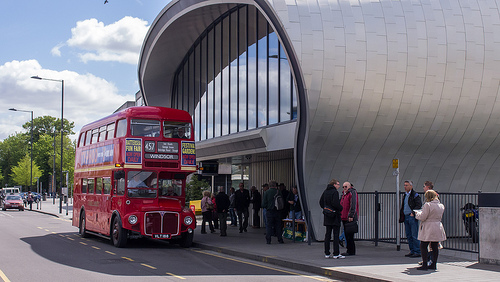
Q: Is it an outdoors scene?
A: Yes, it is outdoors.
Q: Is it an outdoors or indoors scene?
A: It is outdoors.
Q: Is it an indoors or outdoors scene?
A: It is outdoors.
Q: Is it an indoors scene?
A: No, it is outdoors.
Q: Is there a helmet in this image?
A: No, there are no helmets.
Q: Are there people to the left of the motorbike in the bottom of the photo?
A: Yes, there is a person to the left of the motorcycle.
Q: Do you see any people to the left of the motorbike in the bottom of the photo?
A: Yes, there is a person to the left of the motorcycle.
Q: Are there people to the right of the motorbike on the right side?
A: No, the person is to the left of the motorbike.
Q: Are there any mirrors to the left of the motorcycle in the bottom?
A: No, there is a person to the left of the motorbike.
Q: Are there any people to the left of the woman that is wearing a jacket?
A: Yes, there is a person to the left of the woman.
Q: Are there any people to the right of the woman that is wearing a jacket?
A: No, the person is to the left of the woman.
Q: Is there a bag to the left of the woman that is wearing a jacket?
A: No, there is a person to the left of the woman.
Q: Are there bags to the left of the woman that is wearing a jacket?
A: No, there is a person to the left of the woman.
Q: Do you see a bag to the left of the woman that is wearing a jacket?
A: No, there is a person to the left of the woman.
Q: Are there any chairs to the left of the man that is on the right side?
A: No, there is a person to the left of the man.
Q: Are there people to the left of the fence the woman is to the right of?
A: Yes, there is a person to the left of the fence.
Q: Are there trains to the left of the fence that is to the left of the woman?
A: No, there is a person to the left of the fence.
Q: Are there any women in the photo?
A: Yes, there is a woman.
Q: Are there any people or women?
A: Yes, there is a woman.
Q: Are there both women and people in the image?
A: Yes, there are both a woman and people.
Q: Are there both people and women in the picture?
A: Yes, there are both a woman and people.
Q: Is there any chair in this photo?
A: No, there are no chairs.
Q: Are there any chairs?
A: No, there are no chairs.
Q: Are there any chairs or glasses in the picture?
A: No, there are no chairs or glasses.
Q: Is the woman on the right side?
A: Yes, the woman is on the right of the image.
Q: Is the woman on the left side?
A: No, the woman is on the right of the image.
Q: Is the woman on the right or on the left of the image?
A: The woman is on the right of the image.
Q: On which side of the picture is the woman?
A: The woman is on the right of the image.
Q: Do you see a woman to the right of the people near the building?
A: Yes, there is a woman to the right of the people.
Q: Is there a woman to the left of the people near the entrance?
A: No, the woman is to the right of the people.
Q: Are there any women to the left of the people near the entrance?
A: No, the woman is to the right of the people.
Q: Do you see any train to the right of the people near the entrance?
A: No, there is a woman to the right of the people.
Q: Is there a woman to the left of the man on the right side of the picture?
A: Yes, there is a woman to the left of the man.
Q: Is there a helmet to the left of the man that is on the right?
A: No, there is a woman to the left of the man.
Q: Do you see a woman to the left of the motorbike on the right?
A: Yes, there is a woman to the left of the motorbike.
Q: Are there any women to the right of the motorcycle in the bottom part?
A: No, the woman is to the left of the motorbike.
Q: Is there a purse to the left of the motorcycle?
A: No, there is a woman to the left of the motorcycle.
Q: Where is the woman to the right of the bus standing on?
A: The woman is standing on the sidewalk.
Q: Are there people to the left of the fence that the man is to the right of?
A: Yes, there are people to the left of the fence.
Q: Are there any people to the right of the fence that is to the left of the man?
A: No, the people are to the left of the fence.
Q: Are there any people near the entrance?
A: Yes, there are people near the entrance.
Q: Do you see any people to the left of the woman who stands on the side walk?
A: Yes, there are people to the left of the woman.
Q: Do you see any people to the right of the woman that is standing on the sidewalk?
A: No, the people are to the left of the woman.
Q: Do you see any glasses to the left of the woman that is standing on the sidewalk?
A: No, there are people to the left of the woman.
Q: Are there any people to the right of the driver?
A: Yes, there are people to the right of the driver.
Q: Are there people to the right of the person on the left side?
A: Yes, there are people to the right of the driver.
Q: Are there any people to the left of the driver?
A: No, the people are to the right of the driver.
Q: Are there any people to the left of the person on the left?
A: No, the people are to the right of the driver.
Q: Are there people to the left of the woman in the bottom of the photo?
A: Yes, there are people to the left of the woman.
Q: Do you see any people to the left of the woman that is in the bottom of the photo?
A: Yes, there are people to the left of the woman.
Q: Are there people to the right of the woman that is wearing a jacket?
A: No, the people are to the left of the woman.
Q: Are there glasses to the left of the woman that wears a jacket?
A: No, there are people to the left of the woman.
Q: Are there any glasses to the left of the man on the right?
A: No, there are people to the left of the man.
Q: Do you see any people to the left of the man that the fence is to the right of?
A: Yes, there are people to the left of the man.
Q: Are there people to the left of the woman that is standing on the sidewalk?
A: Yes, there is a person to the left of the woman.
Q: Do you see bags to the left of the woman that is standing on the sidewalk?
A: No, there is a person to the left of the woman.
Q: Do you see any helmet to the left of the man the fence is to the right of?
A: No, there is a person to the left of the man.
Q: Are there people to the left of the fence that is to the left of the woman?
A: Yes, there is a person to the left of the fence.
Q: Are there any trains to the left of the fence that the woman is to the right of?
A: No, there is a person to the left of the fence.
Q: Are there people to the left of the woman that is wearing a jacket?
A: Yes, there is a person to the left of the woman.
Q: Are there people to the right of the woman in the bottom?
A: No, the person is to the left of the woman.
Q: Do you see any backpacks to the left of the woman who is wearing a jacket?
A: No, there is a person to the left of the woman.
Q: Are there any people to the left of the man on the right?
A: Yes, there is a person to the left of the man.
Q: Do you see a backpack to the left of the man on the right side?
A: No, there is a person to the left of the man.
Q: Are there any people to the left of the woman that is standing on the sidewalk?
A: Yes, there is a person to the left of the woman.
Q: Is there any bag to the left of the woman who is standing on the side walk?
A: No, there is a person to the left of the woman.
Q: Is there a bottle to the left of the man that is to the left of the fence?
A: No, there is a person to the left of the man.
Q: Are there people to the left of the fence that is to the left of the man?
A: Yes, there is a person to the left of the fence.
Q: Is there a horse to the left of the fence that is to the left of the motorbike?
A: No, there is a person to the left of the fence.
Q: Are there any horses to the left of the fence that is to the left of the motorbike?
A: No, there is a person to the left of the fence.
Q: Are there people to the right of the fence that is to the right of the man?
A: Yes, there is a person to the right of the fence.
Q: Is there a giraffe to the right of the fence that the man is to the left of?
A: No, there is a person to the right of the fence.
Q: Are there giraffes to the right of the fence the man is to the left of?
A: No, there is a person to the right of the fence.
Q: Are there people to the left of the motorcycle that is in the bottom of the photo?
A: Yes, there is a person to the left of the motorbike.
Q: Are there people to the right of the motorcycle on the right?
A: No, the person is to the left of the motorcycle.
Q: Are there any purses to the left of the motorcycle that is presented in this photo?
A: No, there is a person to the left of the motorcycle.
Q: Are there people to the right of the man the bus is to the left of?
A: Yes, there is a person to the right of the man.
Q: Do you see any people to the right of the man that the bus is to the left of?
A: Yes, there is a person to the right of the man.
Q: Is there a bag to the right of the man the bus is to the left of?
A: No, there is a person to the right of the man.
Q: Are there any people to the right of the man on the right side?
A: Yes, there is a person to the right of the man.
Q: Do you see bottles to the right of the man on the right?
A: No, there is a person to the right of the man.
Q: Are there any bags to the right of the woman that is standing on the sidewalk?
A: No, there is a person to the right of the woman.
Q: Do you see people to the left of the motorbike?
A: Yes, there are people to the left of the motorbike.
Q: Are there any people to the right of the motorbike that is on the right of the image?
A: No, the people are to the left of the motorbike.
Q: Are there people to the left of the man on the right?
A: Yes, there are people to the left of the man.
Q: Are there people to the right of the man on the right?
A: No, the people are to the left of the man.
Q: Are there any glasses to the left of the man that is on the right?
A: No, there are people to the left of the man.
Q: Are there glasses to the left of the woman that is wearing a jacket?
A: No, there are people to the left of the woman.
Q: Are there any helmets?
A: No, there are no helmets.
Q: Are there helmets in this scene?
A: No, there are no helmets.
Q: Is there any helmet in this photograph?
A: No, there are no helmets.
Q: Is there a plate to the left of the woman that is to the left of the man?
A: No, there is a person to the left of the woman.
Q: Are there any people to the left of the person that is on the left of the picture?
A: No, the person is to the right of the driver.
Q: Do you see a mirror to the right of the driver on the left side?
A: No, there is a person to the right of the driver.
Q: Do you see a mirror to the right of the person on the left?
A: No, there is a person to the right of the driver.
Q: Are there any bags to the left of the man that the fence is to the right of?
A: No, there is a person to the left of the man.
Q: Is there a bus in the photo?
A: Yes, there is a bus.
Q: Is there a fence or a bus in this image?
A: Yes, there is a bus.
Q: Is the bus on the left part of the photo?
A: Yes, the bus is on the left of the image.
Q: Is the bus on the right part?
A: No, the bus is on the left of the image.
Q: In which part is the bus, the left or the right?
A: The bus is on the left of the image.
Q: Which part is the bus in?
A: The bus is on the left of the image.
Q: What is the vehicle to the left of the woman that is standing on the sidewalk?
A: The vehicle is a bus.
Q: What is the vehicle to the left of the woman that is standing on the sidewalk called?
A: The vehicle is a bus.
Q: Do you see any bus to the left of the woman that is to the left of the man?
A: Yes, there is a bus to the left of the woman.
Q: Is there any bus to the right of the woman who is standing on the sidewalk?
A: No, the bus is to the left of the woman.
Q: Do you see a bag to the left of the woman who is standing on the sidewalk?
A: No, there is a bus to the left of the woman.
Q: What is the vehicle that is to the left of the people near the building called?
A: The vehicle is a bus.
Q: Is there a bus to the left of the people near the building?
A: Yes, there is a bus to the left of the people.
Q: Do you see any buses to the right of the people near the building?
A: No, the bus is to the left of the people.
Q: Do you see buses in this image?
A: Yes, there is a bus.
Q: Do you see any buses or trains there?
A: Yes, there is a bus.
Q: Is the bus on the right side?
A: No, the bus is on the left of the image.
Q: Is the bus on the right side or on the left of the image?
A: The bus is on the left of the image.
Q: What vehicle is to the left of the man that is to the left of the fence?
A: The vehicle is a bus.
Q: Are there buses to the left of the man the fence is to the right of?
A: Yes, there is a bus to the left of the man.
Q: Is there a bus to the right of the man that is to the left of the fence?
A: No, the bus is to the left of the man.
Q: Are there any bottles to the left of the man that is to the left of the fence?
A: No, there is a bus to the left of the man.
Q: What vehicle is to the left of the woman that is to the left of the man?
A: The vehicle is a bus.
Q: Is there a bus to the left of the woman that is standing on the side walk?
A: Yes, there is a bus to the left of the woman.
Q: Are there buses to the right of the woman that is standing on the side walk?
A: No, the bus is to the left of the woman.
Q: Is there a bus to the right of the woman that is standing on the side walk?
A: No, the bus is to the left of the woman.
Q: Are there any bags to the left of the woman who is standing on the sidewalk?
A: No, there is a bus to the left of the woman.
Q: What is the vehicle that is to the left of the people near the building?
A: The vehicle is a bus.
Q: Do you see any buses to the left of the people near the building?
A: Yes, there is a bus to the left of the people.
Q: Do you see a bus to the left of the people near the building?
A: Yes, there is a bus to the left of the people.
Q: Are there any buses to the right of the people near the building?
A: No, the bus is to the left of the people.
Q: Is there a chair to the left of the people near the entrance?
A: No, there is a bus to the left of the people.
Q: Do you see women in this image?
A: Yes, there is a woman.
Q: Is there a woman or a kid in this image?
A: Yes, there is a woman.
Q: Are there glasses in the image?
A: No, there are no glasses.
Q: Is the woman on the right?
A: Yes, the woman is on the right of the image.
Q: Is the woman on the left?
A: No, the woman is on the right of the image.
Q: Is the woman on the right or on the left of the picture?
A: The woman is on the right of the image.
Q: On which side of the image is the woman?
A: The woman is on the right of the image.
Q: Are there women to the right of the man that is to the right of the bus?
A: Yes, there is a woman to the right of the man.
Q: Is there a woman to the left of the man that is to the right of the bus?
A: No, the woman is to the right of the man.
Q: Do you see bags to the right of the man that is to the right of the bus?
A: No, there is a woman to the right of the man.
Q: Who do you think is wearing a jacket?
A: The woman is wearing a jacket.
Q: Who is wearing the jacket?
A: The woman is wearing a jacket.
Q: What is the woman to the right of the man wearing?
A: The woman is wearing a jacket.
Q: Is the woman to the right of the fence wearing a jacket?
A: Yes, the woman is wearing a jacket.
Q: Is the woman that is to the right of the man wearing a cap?
A: No, the woman is wearing a jacket.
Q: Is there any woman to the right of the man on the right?
A: Yes, there is a woman to the right of the man.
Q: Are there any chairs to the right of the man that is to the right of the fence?
A: No, there is a woman to the right of the man.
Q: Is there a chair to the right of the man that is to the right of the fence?
A: No, there is a woman to the right of the man.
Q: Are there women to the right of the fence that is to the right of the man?
A: Yes, there is a woman to the right of the fence.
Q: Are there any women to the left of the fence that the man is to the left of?
A: No, the woman is to the right of the fence.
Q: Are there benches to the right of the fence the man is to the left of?
A: No, there is a woman to the right of the fence.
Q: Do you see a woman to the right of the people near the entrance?
A: Yes, there is a woman to the right of the people.